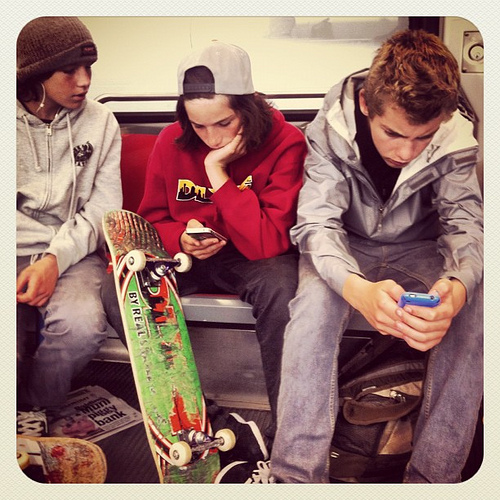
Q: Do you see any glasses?
A: No, there are no glasses.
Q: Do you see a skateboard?
A: Yes, there is a skateboard.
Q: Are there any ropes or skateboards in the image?
A: Yes, there is a skateboard.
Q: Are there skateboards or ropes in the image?
A: Yes, there is a skateboard.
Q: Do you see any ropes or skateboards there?
A: Yes, there is a skateboard.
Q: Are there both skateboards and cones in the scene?
A: No, there is a skateboard but no cones.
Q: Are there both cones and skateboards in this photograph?
A: No, there is a skateboard but no cones.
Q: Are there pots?
A: No, there are no pots.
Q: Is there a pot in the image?
A: No, there are no pots.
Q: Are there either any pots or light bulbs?
A: No, there are no pots or light bulbs.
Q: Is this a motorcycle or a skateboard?
A: This is a skateboard.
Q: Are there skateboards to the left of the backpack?
A: Yes, there is a skateboard to the left of the backpack.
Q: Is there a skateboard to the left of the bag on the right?
A: Yes, there is a skateboard to the left of the backpack.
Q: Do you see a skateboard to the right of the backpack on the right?
A: No, the skateboard is to the left of the backpack.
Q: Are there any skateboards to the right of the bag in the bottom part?
A: No, the skateboard is to the left of the backpack.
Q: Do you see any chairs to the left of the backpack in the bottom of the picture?
A: No, there is a skateboard to the left of the backpack.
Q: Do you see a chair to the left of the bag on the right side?
A: No, there is a skateboard to the left of the backpack.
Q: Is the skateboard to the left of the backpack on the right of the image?
A: Yes, the skateboard is to the left of the backpack.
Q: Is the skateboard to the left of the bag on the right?
A: Yes, the skateboard is to the left of the backpack.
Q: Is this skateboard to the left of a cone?
A: No, the skateboard is to the left of the backpack.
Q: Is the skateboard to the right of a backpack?
A: No, the skateboard is to the left of a backpack.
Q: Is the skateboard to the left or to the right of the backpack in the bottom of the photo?
A: The skateboard is to the left of the backpack.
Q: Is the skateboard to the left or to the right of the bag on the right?
A: The skateboard is to the left of the backpack.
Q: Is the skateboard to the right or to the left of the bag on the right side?
A: The skateboard is to the left of the backpack.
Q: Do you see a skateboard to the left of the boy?
A: Yes, there is a skateboard to the left of the boy.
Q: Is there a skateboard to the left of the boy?
A: Yes, there is a skateboard to the left of the boy.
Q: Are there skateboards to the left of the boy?
A: Yes, there is a skateboard to the left of the boy.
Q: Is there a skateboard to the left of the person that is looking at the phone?
A: Yes, there is a skateboard to the left of the boy.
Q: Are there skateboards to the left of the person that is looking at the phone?
A: Yes, there is a skateboard to the left of the boy.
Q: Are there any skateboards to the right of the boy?
A: No, the skateboard is to the left of the boy.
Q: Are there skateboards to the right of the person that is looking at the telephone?
A: No, the skateboard is to the left of the boy.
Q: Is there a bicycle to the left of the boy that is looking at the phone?
A: No, there is a skateboard to the left of the boy.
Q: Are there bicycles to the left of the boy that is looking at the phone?
A: No, there is a skateboard to the left of the boy.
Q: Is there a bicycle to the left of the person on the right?
A: No, there is a skateboard to the left of the boy.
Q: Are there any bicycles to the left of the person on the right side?
A: No, there is a skateboard to the left of the boy.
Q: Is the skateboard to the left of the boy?
A: Yes, the skateboard is to the left of the boy.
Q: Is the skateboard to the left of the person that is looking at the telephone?
A: Yes, the skateboard is to the left of the boy.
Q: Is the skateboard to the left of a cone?
A: No, the skateboard is to the left of the boy.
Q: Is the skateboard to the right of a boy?
A: No, the skateboard is to the left of a boy.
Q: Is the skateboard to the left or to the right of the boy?
A: The skateboard is to the left of the boy.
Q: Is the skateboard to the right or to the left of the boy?
A: The skateboard is to the left of the boy.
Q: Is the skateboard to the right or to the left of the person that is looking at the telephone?
A: The skateboard is to the left of the boy.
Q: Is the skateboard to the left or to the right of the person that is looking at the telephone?
A: The skateboard is to the left of the boy.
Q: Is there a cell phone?
A: Yes, there is a cell phone.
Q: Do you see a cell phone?
A: Yes, there is a cell phone.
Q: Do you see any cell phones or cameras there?
A: Yes, there is a cell phone.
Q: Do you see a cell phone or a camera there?
A: Yes, there is a cell phone.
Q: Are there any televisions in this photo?
A: No, there are no televisions.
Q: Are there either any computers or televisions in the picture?
A: No, there are no televisions or computers.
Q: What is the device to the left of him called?
A: The device is a cell phone.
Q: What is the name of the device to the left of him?
A: The device is a cell phone.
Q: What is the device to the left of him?
A: The device is a cell phone.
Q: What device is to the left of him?
A: The device is a cell phone.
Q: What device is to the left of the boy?
A: The device is a cell phone.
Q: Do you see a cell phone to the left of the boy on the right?
A: Yes, there is a cell phone to the left of the boy.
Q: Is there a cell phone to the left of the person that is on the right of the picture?
A: Yes, there is a cell phone to the left of the boy.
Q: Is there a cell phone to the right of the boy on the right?
A: No, the cell phone is to the left of the boy.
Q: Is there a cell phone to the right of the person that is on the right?
A: No, the cell phone is to the left of the boy.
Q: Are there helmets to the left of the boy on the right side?
A: No, there is a cell phone to the left of the boy.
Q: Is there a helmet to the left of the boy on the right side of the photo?
A: No, there is a cell phone to the left of the boy.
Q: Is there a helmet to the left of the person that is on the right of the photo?
A: No, there is a cell phone to the left of the boy.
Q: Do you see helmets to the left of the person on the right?
A: No, there is a cell phone to the left of the boy.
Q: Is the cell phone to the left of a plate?
A: No, the cell phone is to the left of a boy.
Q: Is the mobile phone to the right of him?
A: No, the mobile phone is to the left of the boy.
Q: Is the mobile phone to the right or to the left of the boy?
A: The mobile phone is to the left of the boy.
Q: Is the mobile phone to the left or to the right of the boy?
A: The mobile phone is to the left of the boy.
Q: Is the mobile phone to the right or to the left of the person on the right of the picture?
A: The mobile phone is to the left of the boy.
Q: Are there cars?
A: No, there are no cars.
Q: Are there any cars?
A: No, there are no cars.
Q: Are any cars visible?
A: No, there are no cars.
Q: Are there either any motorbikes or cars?
A: No, there are no cars or motorbikes.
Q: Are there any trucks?
A: Yes, there is a truck.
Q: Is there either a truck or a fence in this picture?
A: Yes, there is a truck.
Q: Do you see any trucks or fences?
A: Yes, there is a truck.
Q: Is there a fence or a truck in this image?
A: Yes, there is a truck.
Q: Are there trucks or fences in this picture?
A: Yes, there is a truck.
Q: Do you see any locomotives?
A: No, there are no locomotives.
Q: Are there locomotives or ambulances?
A: No, there are no locomotives or ambulances.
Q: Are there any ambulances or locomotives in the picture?
A: No, there are no locomotives or ambulances.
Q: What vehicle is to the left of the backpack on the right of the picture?
A: The vehicle is a truck.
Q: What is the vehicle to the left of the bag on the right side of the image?
A: The vehicle is a truck.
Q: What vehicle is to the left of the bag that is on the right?
A: The vehicle is a truck.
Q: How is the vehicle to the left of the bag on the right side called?
A: The vehicle is a truck.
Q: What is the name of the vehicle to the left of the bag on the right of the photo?
A: The vehicle is a truck.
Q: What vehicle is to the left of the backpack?
A: The vehicle is a truck.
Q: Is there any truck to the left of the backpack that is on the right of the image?
A: Yes, there is a truck to the left of the backpack.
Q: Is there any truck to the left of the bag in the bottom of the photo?
A: Yes, there is a truck to the left of the backpack.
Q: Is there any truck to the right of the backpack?
A: No, the truck is to the left of the backpack.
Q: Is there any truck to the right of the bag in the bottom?
A: No, the truck is to the left of the backpack.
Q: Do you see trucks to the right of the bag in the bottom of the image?
A: No, the truck is to the left of the backpack.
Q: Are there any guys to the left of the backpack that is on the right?
A: No, there is a truck to the left of the backpack.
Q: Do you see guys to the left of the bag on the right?
A: No, there is a truck to the left of the backpack.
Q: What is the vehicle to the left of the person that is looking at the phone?
A: The vehicle is a truck.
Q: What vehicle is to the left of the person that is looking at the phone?
A: The vehicle is a truck.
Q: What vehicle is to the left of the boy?
A: The vehicle is a truck.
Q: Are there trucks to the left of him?
A: Yes, there is a truck to the left of the boy.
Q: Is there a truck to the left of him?
A: Yes, there is a truck to the left of the boy.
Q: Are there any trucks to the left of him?
A: Yes, there is a truck to the left of the boy.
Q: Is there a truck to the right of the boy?
A: No, the truck is to the left of the boy.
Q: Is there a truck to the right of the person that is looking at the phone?
A: No, the truck is to the left of the boy.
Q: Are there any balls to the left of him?
A: No, there is a truck to the left of the boy.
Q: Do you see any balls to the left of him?
A: No, there is a truck to the left of the boy.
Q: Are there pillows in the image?
A: No, there are no pillows.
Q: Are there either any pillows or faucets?
A: No, there are no pillows or faucets.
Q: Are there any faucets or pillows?
A: No, there are no pillows or faucets.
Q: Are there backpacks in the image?
A: Yes, there is a backpack.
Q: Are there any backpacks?
A: Yes, there is a backpack.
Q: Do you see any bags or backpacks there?
A: Yes, there is a backpack.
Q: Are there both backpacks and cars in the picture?
A: No, there is a backpack but no cars.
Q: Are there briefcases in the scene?
A: No, there are no briefcases.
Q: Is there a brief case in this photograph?
A: No, there are no briefcases.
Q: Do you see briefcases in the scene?
A: No, there are no briefcases.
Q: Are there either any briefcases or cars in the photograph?
A: No, there are no briefcases or cars.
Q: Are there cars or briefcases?
A: No, there are no briefcases or cars.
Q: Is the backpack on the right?
A: Yes, the backpack is on the right of the image.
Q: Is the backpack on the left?
A: No, the backpack is on the right of the image.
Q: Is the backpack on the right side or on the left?
A: The backpack is on the right of the image.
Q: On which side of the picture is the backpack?
A: The backpack is on the right of the image.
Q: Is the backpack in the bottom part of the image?
A: Yes, the backpack is in the bottom of the image.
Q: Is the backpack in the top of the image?
A: No, the backpack is in the bottom of the image.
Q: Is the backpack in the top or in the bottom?
A: The backpack is in the bottom of the image.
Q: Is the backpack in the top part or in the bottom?
A: The backpack is in the bottom of the image.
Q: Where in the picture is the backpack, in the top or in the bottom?
A: The backpack is in the bottom of the image.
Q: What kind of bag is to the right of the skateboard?
A: The bag is a backpack.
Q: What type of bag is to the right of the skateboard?
A: The bag is a backpack.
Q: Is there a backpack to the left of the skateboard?
A: No, the backpack is to the right of the skateboard.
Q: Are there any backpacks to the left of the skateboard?
A: No, the backpack is to the right of the skateboard.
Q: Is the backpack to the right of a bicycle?
A: No, the backpack is to the right of the skateboard.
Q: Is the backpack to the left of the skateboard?
A: No, the backpack is to the right of the skateboard.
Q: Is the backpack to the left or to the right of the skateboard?
A: The backpack is to the right of the skateboard.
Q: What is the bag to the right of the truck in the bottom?
A: The bag is a backpack.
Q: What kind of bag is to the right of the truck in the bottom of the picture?
A: The bag is a backpack.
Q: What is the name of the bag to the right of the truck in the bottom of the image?
A: The bag is a backpack.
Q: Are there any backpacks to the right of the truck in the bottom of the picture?
A: Yes, there is a backpack to the right of the truck.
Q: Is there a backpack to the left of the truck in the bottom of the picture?
A: No, the backpack is to the right of the truck.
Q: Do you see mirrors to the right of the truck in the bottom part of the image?
A: No, there is a backpack to the right of the truck.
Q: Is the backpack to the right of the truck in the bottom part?
A: Yes, the backpack is to the right of the truck.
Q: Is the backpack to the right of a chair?
A: No, the backpack is to the right of the truck.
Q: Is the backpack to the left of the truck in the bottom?
A: No, the backpack is to the right of the truck.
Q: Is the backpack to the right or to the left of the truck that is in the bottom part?
A: The backpack is to the right of the truck.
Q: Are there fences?
A: No, there are no fences.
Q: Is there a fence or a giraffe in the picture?
A: No, there are no fences or giraffes.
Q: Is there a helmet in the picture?
A: No, there are no helmets.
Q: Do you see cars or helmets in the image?
A: No, there are no helmets or cars.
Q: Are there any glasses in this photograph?
A: No, there are no glasses.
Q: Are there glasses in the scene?
A: No, there are no glasses.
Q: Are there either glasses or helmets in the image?
A: No, there are no glasses or helmets.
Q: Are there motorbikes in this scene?
A: No, there are no motorbikes.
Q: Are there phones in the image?
A: Yes, there is a phone.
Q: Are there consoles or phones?
A: Yes, there is a phone.